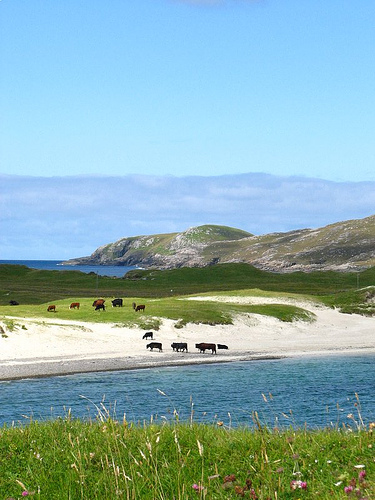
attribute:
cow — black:
[215, 340, 231, 354]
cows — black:
[139, 336, 231, 356]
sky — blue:
[11, 10, 366, 174]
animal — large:
[170, 338, 192, 350]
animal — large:
[213, 338, 233, 350]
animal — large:
[170, 342, 189, 352]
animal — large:
[145, 341, 164, 352]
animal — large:
[142, 331, 152, 339]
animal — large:
[132, 301, 136, 310]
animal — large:
[111, 295, 124, 308]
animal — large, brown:
[91, 298, 104, 304]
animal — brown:
[67, 298, 81, 311]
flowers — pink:
[9, 462, 373, 497]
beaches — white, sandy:
[0, 297, 370, 378]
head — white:
[67, 305, 71, 308]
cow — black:
[144, 342, 162, 352]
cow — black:
[217, 344, 228, 348]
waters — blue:
[0, 260, 142, 277]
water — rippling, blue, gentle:
[0, 355, 372, 427]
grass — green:
[0, 394, 372, 498]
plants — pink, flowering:
[2, 389, 371, 498]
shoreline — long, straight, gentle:
[2, 339, 374, 383]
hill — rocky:
[57, 218, 374, 272]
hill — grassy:
[144, 222, 253, 267]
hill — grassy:
[200, 224, 311, 266]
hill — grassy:
[272, 211, 373, 270]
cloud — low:
[0, 170, 373, 262]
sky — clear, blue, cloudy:
[0, 0, 370, 259]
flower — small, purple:
[220, 471, 237, 485]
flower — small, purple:
[296, 479, 311, 491]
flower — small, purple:
[191, 482, 201, 492]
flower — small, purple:
[341, 484, 352, 492]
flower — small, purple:
[357, 467, 367, 478]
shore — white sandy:
[103, 319, 294, 357]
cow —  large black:
[140, 330, 223, 354]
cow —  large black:
[172, 339, 188, 353]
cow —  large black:
[168, 339, 227, 361]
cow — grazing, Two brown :
[162, 339, 228, 353]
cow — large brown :
[147, 336, 223, 354]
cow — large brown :
[146, 331, 225, 356]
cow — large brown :
[139, 339, 222, 359]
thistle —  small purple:
[193, 464, 302, 493]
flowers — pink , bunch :
[229, 460, 361, 498]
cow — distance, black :
[140, 330, 217, 356]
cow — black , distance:
[132, 330, 230, 355]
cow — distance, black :
[134, 328, 235, 360]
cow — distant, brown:
[69, 300, 80, 309]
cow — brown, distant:
[45, 304, 55, 312]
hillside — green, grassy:
[1, 388, 373, 497]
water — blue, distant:
[0, 259, 145, 276]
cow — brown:
[194, 341, 215, 355]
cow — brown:
[171, 339, 190, 352]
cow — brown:
[146, 340, 165, 350]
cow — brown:
[142, 330, 154, 338]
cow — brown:
[133, 302, 148, 312]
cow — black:
[112, 296, 124, 306]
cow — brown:
[92, 297, 104, 305]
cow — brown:
[68, 300, 80, 312]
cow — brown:
[47, 306, 57, 311]